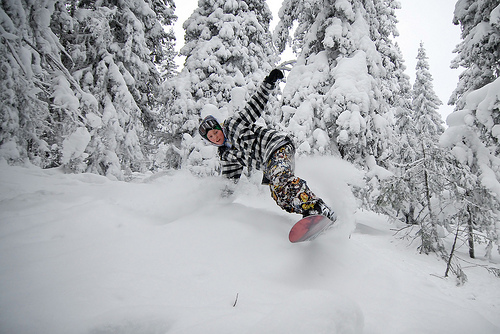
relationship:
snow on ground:
[59, 200, 168, 296] [218, 240, 441, 318]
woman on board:
[177, 98, 321, 204] [291, 215, 332, 260]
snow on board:
[59, 200, 168, 296] [291, 215, 332, 260]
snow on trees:
[59, 200, 168, 296] [200, 6, 384, 58]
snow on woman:
[59, 200, 168, 296] [177, 98, 321, 204]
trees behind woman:
[200, 6, 384, 58] [177, 98, 321, 204]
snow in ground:
[59, 200, 168, 296] [218, 240, 441, 318]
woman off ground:
[177, 98, 321, 204] [218, 240, 441, 318]